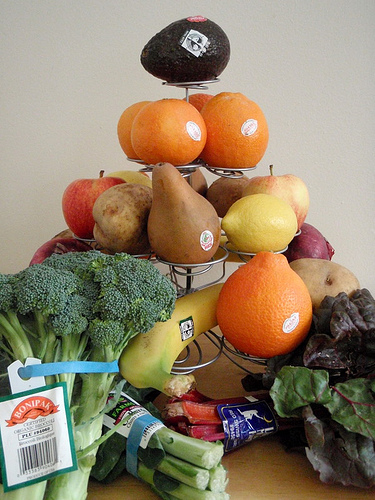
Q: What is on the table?
A: A tower tray.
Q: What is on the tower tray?
A: Fruit.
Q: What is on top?
A: An avocado.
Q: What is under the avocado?
A: Oranges.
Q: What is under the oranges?
A: A fruit mixture.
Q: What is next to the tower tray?
A: Broccoli.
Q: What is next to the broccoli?
A: A banana.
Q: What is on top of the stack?
A: An avocado.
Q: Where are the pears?
A: Third tier.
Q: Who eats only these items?
A: Vegans.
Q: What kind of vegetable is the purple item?
A: Lettuce.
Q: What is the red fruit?
A: Apple.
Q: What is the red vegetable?
A: Onion.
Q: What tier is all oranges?
A: Second from top.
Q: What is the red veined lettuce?
A: Radicchio.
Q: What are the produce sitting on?
A: A multi tiered cupcake rack.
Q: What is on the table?
A: Food.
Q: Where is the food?
A: On the table.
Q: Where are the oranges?
A: Below the avocado.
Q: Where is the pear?
A: On the second rack.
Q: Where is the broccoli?
A: On the table.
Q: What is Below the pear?
A: The banana.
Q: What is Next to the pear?
A: A potato.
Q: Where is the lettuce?
A: On the table.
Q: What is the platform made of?
A: Wire.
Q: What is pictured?
A: Produce.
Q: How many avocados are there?
A: One.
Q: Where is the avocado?
A: Top.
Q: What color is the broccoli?
A: Green.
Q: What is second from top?
A: Orange.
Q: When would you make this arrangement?
A: Display.